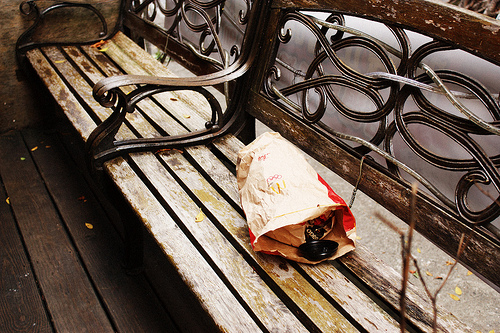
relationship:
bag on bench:
[229, 128, 351, 257] [94, 0, 498, 332]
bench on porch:
[94, 0, 498, 332] [3, 121, 209, 332]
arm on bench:
[91, 57, 241, 166] [94, 0, 498, 332]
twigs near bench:
[322, 125, 476, 332] [94, 0, 498, 332]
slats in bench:
[127, 130, 404, 332] [94, 0, 498, 332]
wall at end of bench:
[1, 5, 112, 143] [18, 1, 243, 163]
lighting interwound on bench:
[269, 16, 499, 211] [94, 0, 498, 332]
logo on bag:
[266, 169, 298, 202] [229, 128, 351, 257]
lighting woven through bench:
[269, 16, 499, 211] [94, 0, 498, 332]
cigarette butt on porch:
[31, 142, 41, 159] [3, 121, 209, 332]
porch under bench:
[3, 121, 209, 332] [94, 0, 498, 332]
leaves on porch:
[7, 133, 99, 234] [3, 121, 209, 332]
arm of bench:
[91, 57, 241, 166] [94, 0, 498, 332]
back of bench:
[254, 1, 499, 267] [94, 0, 498, 332]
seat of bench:
[117, 141, 455, 332] [94, 0, 498, 332]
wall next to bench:
[1, 5, 112, 143] [18, 1, 243, 163]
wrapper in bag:
[275, 221, 344, 245] [229, 128, 351, 257]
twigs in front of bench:
[322, 125, 476, 332] [94, 0, 498, 332]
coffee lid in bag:
[294, 236, 334, 261] [229, 128, 351, 257]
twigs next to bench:
[322, 125, 476, 332] [94, 0, 498, 332]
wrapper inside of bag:
[275, 221, 344, 245] [229, 128, 351, 257]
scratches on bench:
[133, 154, 242, 231] [94, 0, 498, 332]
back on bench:
[254, 1, 499, 267] [94, 0, 498, 332]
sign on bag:
[314, 177, 358, 233] [229, 128, 351, 257]